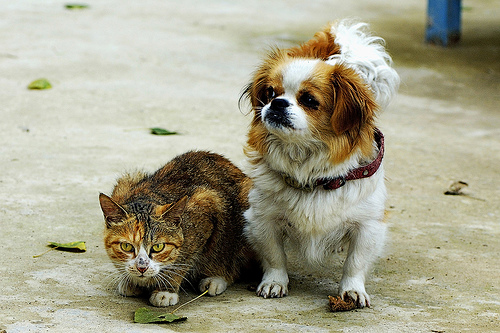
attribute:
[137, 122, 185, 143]
leaf — green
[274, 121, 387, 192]
collar — red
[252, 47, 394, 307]
dog — small, white, brown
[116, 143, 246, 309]
cat — tabby, brown, white, looking, gold, grey, orange, multicolored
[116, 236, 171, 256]
eyes — green, yellow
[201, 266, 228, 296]
paw — white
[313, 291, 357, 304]
leaf — brown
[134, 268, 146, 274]
nose — pink, small, white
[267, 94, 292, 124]
nose — black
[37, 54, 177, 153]
leaves — green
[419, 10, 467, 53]
pole — blue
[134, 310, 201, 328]
leaf — green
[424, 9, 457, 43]
leg — blue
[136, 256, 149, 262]
dots — black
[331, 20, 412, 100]
tail — fluffy, white, brown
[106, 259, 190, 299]
whiskers — white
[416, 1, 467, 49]
post — blue, square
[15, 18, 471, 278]
concrete — old, worn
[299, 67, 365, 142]
patches — white, orange